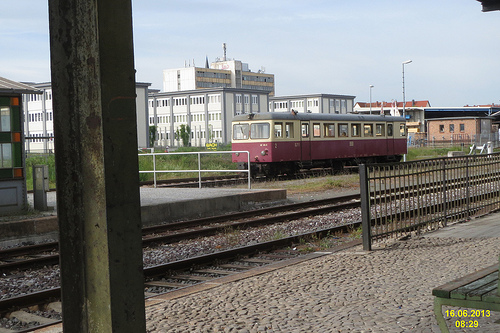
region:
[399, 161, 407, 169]
part of a rail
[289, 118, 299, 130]
part of a train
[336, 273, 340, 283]
part of a floor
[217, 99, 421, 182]
red and yellow train car stopped on track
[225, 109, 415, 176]
many windows on old train car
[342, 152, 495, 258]
iron fence along train track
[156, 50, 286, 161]
old building in background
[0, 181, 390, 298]
empty train tracks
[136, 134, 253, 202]
white iron barricade on platform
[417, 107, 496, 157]
brown building in background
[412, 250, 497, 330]
corner of bench along train tracks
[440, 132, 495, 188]
pieces of metal in background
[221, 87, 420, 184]
train on the track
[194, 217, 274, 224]
track with no train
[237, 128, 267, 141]
windows on the train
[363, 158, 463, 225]
metal fence near track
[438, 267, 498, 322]
bench near the track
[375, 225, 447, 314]
concrete area outside of track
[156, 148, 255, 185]
rail on the concrete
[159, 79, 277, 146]
building near the track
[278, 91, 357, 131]
building near the track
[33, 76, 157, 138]
building near the track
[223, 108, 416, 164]
red train on the railroad tracks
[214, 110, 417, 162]
red train on the railroad tracks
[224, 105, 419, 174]
red train on the railroad tracks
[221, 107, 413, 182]
red train on the railroad tracks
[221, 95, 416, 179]
red train on the railroad tracks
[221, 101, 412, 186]
red train on the railroad tracks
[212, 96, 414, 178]
red train on the railroad tracks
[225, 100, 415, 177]
red train on the railroad tracks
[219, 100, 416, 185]
red train on the railroad tracks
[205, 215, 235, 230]
train tracks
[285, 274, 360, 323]
rocks that are grey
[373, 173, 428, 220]
a metal fence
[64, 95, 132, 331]
a pole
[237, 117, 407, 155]
a train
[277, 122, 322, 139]
windows on the train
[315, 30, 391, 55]
a clear blue sky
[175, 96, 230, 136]
a building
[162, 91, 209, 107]
the building has windows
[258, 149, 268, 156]
the headlight on the train is clear